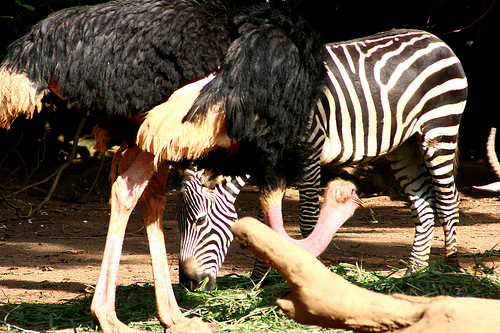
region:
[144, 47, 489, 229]
A bird is next to a zebra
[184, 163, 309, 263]
The zebra is black and white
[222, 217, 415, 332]
A wooden trunk is next to the animals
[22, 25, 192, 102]
The bird has black feathers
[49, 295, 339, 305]
They are standing on green grass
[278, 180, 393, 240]
An ostrich is next to the zebra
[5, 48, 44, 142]
The ostrich has a brown tail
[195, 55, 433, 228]
The ostrich is hovering onver the zebra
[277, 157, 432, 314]
The ostrich has an orange nose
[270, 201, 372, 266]
The ostrich has a pink neck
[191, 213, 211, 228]
Eye of striped zebra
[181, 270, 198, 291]
Nose of striped zebra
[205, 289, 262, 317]
Grassy area for zebra meal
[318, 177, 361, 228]
Head of curious ostrich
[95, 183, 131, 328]
Par of ostrich's leg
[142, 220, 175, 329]
Part of ostrich's leg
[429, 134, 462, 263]
Part of zebra's leg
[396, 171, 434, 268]
Part of zebra's leg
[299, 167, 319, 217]
Part of zebra's leg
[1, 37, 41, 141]
Tail area of curious ostrich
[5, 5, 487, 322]
Ostrich and a zebra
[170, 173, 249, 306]
The zebra is eating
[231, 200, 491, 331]
Large tree branch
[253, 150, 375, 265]
The ostrich's neck is curved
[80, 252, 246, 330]
The ostrich is standing on grass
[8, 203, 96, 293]
The ground is mostly covered by dirt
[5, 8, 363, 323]
Only the right side of the ostrich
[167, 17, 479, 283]
Only the left side of the zebra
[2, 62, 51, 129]
Yellow patch of fur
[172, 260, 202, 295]
The zebra's nose is on the ground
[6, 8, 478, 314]
a zebra behind a ostrich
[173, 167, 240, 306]
zebra eats green grass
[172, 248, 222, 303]
muzzle of zebra is black and brown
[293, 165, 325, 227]
front leg of zebra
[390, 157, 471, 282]
back legs of zebra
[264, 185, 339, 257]
long neck of ostrich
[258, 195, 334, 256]
neck of ostrich is pink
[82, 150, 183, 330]
legs of ostrich are pink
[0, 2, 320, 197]
feathers of ostrich are black and brown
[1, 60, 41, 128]
tail of ostrich is yellow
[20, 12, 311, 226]
the ostrich is black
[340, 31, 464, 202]
the zebra is black and white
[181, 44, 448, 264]
the zebra is grazing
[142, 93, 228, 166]
the feathers are brown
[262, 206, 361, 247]
the neck is curved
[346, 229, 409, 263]
shadow is on the ground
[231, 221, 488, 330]
the log is brown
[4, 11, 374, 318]
the ostrcih is a big bird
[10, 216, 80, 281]
the ground is brown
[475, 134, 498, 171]
the horns are brown